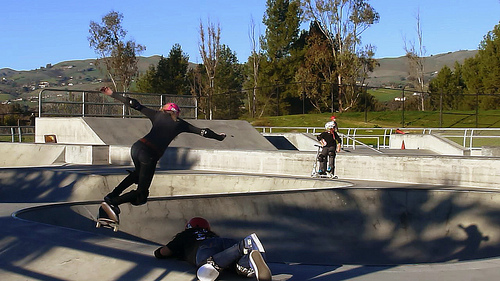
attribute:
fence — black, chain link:
[356, 82, 498, 126]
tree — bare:
[399, 5, 436, 117]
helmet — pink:
[158, 100, 179, 111]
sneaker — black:
[103, 195, 120, 215]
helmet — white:
[143, 97, 205, 124]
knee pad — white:
[126, 181, 166, 208]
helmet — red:
[183, 217, 213, 229]